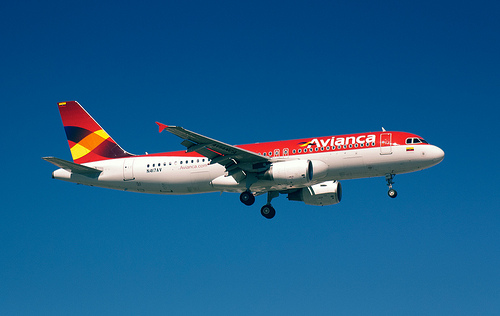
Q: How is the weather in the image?
A: It is clear.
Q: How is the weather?
A: It is clear.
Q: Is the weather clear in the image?
A: Yes, it is clear.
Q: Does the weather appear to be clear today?
A: Yes, it is clear.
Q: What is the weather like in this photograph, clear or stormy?
A: It is clear.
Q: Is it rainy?
A: No, it is clear.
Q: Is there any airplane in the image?
A: Yes, there is an airplane.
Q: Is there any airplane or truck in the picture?
A: Yes, there is an airplane.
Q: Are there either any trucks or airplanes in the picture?
A: Yes, there is an airplane.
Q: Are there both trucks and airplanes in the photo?
A: No, there is an airplane but no trucks.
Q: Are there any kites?
A: No, there are no kites.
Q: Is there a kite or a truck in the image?
A: No, there are no kites or trucks.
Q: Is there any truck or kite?
A: No, there are no kites or trucks.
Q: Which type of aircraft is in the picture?
A: The aircraft is an airplane.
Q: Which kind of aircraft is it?
A: The aircraft is an airplane.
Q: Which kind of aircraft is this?
A: That is an airplane.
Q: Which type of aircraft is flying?
A: The aircraft is an airplane.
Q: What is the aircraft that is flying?
A: The aircraft is an airplane.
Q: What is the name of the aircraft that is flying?
A: The aircraft is an airplane.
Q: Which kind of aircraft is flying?
A: The aircraft is an airplane.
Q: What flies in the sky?
A: The airplane flies in the sky.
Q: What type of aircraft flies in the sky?
A: The aircraft is an airplane.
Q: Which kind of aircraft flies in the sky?
A: The aircraft is an airplane.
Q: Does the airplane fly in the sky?
A: Yes, the airplane flies in the sky.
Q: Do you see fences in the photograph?
A: No, there are no fences.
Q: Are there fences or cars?
A: No, there are no fences or cars.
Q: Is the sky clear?
A: Yes, the sky is clear.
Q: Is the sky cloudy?
A: No, the sky is clear.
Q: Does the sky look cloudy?
A: No, the sky is clear.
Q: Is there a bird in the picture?
A: No, there are no birds.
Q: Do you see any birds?
A: No, there are no birds.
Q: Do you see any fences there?
A: No, there are no fences.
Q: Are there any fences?
A: No, there are no fences.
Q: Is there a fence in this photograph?
A: No, there are no fences.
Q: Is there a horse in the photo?
A: No, there are no horses.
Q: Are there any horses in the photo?
A: No, there are no horses.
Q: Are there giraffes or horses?
A: No, there are no horses or giraffes.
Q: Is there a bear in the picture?
A: No, there are no bears.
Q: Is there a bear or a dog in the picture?
A: No, there are no bears or dogs.